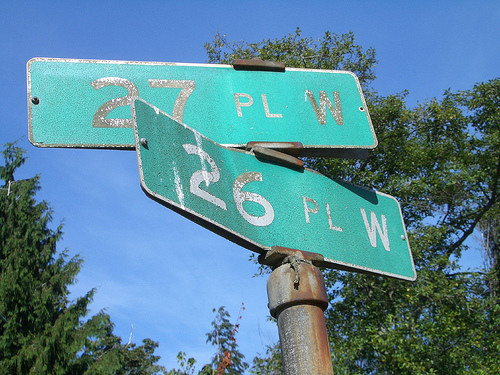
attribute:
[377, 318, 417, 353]
leaf — green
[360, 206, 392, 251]
white "w" — large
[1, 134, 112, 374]
tree — very tall, very dry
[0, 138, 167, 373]
tree — tall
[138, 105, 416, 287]
sign — white, green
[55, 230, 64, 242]
leaf — green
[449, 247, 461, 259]
leaf — green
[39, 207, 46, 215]
leaf — green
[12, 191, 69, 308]
leaves — green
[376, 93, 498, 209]
leaves — green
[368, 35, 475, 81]
sky — blue, clear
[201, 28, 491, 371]
trees — tall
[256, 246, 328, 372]
pole — rusty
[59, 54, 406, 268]
lettering — white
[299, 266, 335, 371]
stain — rust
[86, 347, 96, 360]
leaf — green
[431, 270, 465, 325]
leaves — green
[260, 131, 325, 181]
clips — rusty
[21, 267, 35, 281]
leaves — green